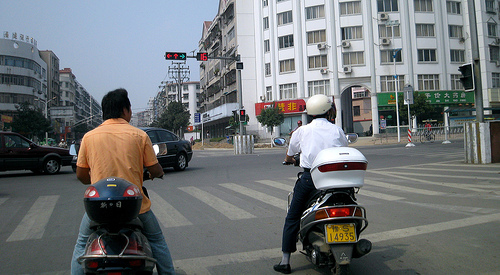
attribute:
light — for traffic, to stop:
[459, 64, 477, 94]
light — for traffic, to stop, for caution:
[166, 53, 189, 60]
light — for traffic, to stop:
[197, 53, 210, 61]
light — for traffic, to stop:
[239, 108, 247, 123]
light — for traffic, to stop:
[236, 62, 244, 70]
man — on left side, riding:
[74, 88, 166, 271]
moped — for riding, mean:
[77, 229, 157, 271]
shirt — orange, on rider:
[74, 119, 158, 214]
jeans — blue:
[69, 208, 175, 271]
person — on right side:
[272, 93, 350, 270]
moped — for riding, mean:
[297, 186, 373, 268]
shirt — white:
[286, 118, 351, 172]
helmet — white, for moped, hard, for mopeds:
[305, 93, 334, 117]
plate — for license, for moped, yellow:
[326, 222, 358, 244]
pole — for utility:
[233, 49, 251, 135]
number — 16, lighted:
[196, 52, 210, 60]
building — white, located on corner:
[235, 3, 479, 140]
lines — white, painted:
[9, 157, 495, 270]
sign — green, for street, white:
[378, 91, 477, 106]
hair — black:
[102, 89, 132, 121]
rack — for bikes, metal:
[414, 125, 465, 138]